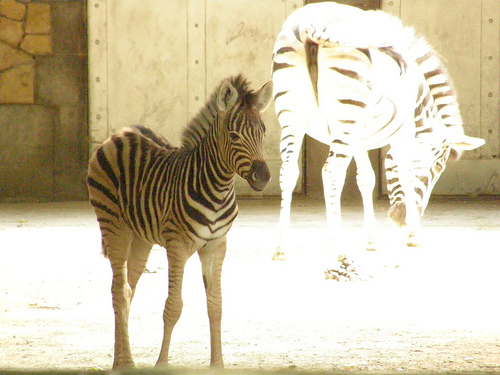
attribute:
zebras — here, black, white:
[81, 4, 490, 371]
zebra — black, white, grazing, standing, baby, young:
[76, 70, 273, 374]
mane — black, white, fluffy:
[180, 97, 214, 151]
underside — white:
[120, 225, 159, 257]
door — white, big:
[85, 3, 205, 126]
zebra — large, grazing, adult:
[262, 3, 493, 234]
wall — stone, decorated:
[3, 4, 87, 149]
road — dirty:
[279, 248, 497, 358]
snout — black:
[248, 159, 272, 191]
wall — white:
[200, 8, 264, 77]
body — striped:
[96, 138, 211, 246]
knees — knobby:
[104, 283, 190, 326]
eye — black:
[229, 129, 242, 144]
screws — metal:
[94, 35, 103, 51]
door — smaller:
[392, 1, 498, 95]